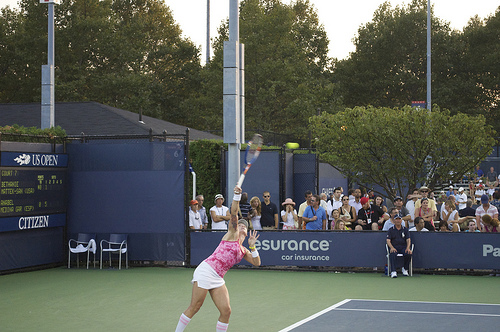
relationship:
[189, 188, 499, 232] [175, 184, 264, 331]
people watching a lady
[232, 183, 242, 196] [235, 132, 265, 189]
hand holding tennis racket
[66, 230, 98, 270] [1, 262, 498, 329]
chair on a tennis court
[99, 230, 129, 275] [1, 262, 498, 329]
chair on a tennis court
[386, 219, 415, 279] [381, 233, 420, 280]
person on chair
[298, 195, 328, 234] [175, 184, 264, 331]
fan watching lady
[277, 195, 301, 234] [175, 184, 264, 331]
fan watching lady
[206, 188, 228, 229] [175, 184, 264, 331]
fan watching lady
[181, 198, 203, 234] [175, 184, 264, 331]
fan watching lady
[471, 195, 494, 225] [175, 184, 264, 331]
fan watching lady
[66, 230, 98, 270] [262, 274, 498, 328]
chair on court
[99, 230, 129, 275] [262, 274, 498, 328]
chair on court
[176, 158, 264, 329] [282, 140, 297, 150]
lady hitting ball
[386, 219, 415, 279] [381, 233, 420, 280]
person sitting in chair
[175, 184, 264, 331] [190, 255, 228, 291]
lady wearing shorts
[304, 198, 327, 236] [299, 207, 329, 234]
person wearing blue shirt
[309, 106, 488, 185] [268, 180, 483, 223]
tree behind audience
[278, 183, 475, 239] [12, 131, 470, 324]
people watching match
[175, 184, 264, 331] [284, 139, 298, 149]
lady serving ball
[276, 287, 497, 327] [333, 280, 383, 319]
court with lines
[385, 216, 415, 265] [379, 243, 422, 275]
judge sitting in chair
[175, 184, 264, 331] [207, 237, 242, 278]
lady wearing pink shirt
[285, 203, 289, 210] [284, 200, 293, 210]
hand held to face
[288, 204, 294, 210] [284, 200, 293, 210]
hand held to face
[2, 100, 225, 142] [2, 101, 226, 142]
roof covering building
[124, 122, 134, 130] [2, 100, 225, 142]
shingle covering roof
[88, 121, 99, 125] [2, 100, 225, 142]
shingle covering roof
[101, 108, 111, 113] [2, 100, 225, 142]
shingle covering roof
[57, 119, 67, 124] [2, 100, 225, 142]
shingle covering roof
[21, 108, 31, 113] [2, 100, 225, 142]
shingle covering roof